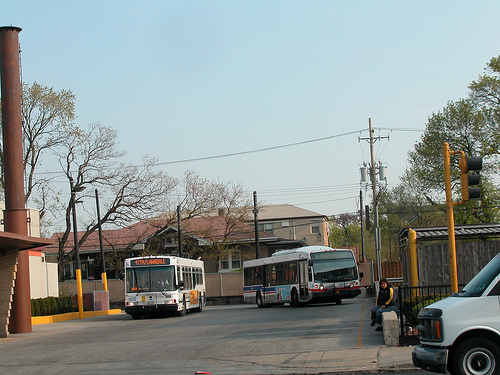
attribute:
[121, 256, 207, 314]
bus — parked, white, public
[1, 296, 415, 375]
road — gray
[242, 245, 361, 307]
bus — white, public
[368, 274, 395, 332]
woman — sitting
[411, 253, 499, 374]
van — white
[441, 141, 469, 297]
pole — orange, yellow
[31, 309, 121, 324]
curb — yellow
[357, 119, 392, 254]
pole — telephone-pole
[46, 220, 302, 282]
building — distant, light-brown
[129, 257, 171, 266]
sign — digital, destination, electronic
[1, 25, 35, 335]
stack — brown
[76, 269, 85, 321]
pole — yellow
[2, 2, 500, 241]
sky — clear, blue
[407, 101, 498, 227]
tree — distant, green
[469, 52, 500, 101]
tree — green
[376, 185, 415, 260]
tree — green